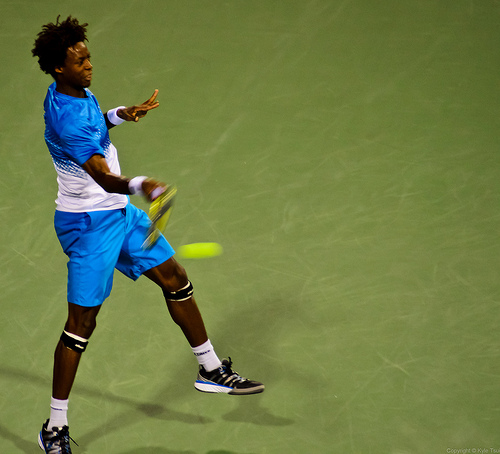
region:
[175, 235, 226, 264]
a yellow tennis ball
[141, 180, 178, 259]
a tennis racket in motion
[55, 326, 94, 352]
a black band on the knee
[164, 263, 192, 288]
the knee of a player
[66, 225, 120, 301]
blue short of a player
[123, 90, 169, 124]
the hand of a player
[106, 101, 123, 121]
a white wrist band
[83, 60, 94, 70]
the nose of a player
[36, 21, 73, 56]
the hair of a player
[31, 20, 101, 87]
the head of a person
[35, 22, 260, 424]
tennis player playing tennis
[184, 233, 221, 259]
green ball in mid air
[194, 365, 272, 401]
black sneaker on foot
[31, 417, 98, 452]
black sneaker on foot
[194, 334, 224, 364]
white sock on man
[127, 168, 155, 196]
white wristband on player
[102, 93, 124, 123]
white wristband on player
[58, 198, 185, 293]
blue shorts on player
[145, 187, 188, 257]
tennis racket in hand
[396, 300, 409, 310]
part of a surface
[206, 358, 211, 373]
part of a sock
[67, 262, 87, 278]
part of a short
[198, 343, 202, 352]
part of a sock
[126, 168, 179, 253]
man holding bat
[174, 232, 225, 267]
it is a ball in air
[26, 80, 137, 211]
man wearing blue with white shirt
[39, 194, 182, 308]
man wearing blue drawer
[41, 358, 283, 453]
man wearing shoe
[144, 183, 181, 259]
it is a green color bat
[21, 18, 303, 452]
man playing tennis on court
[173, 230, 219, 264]
green ball in mid air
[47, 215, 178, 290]
blue shorts on tennis player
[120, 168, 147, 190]
white wrist band on arm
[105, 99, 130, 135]
white wrist band on arm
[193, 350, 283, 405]
black sneakers on tennis player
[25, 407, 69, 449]
black sneakers on tennis player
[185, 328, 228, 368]
white sock on tennis player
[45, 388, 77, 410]
white sock on tennis player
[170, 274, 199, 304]
band around man's knee